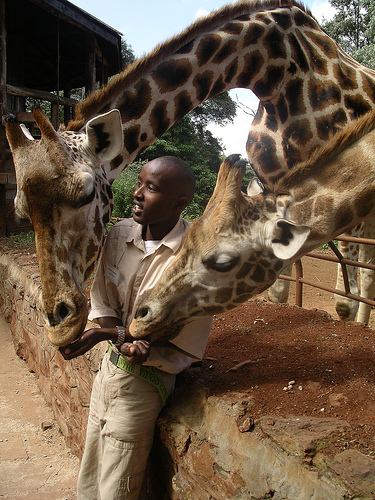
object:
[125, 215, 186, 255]
collar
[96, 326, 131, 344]
man's arm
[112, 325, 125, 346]
watch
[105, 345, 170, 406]
belt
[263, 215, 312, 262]
ear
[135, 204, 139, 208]
teeth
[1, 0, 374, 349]
giraffe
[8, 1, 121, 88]
building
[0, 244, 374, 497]
brick wall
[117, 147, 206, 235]
yellow cab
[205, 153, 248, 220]
horns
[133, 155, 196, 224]
head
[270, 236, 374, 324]
fence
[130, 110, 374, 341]
giraffe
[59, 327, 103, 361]
hand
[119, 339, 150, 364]
hand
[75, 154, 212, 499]
guy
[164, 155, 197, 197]
hair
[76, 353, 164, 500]
pants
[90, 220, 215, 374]
shirt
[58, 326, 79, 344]
snack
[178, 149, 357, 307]
pen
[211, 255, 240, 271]
eye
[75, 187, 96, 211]
eye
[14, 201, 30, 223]
eye